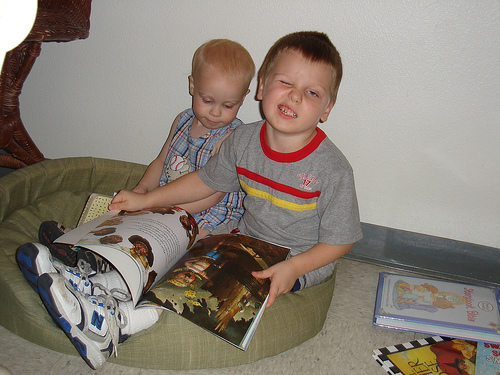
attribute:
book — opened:
[49, 202, 299, 352]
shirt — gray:
[227, 119, 352, 266]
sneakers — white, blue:
[13, 239, 123, 373]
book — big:
[374, 272, 499, 341]